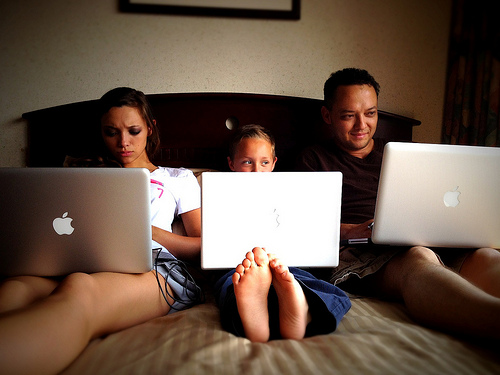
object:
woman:
[0, 86, 202, 375]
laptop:
[0, 164, 155, 276]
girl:
[210, 121, 348, 344]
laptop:
[197, 169, 344, 269]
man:
[297, 66, 499, 337]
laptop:
[368, 140, 498, 249]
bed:
[0, 91, 499, 375]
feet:
[230, 245, 276, 345]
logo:
[52, 209, 76, 238]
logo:
[263, 206, 282, 230]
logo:
[438, 185, 462, 211]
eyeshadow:
[128, 124, 143, 139]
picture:
[115, 2, 304, 23]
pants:
[209, 265, 353, 337]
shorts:
[327, 247, 473, 301]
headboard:
[22, 91, 421, 169]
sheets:
[58, 294, 499, 374]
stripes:
[245, 344, 271, 375]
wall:
[0, 0, 449, 165]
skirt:
[158, 249, 197, 315]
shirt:
[292, 146, 380, 218]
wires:
[151, 246, 193, 311]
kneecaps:
[62, 269, 96, 294]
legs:
[440, 247, 500, 298]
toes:
[230, 272, 243, 291]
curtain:
[442, 5, 497, 145]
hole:
[224, 117, 239, 130]